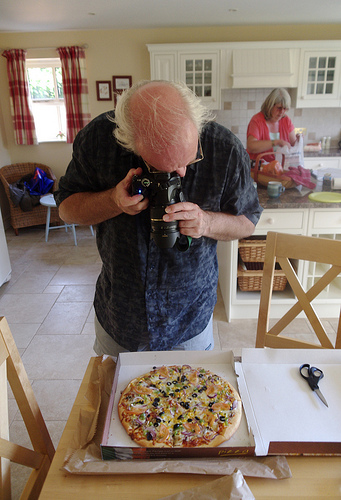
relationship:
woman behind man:
[245, 79, 299, 157] [67, 95, 250, 310]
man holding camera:
[67, 95, 250, 310] [137, 171, 195, 241]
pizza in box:
[134, 365, 244, 448] [104, 343, 274, 475]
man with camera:
[67, 95, 250, 310] [137, 171, 195, 241]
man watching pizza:
[67, 95, 250, 310] [134, 365, 244, 448]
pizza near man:
[134, 365, 244, 448] [67, 95, 250, 310]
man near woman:
[67, 95, 250, 310] [245, 79, 299, 157]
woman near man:
[245, 79, 299, 157] [67, 95, 250, 310]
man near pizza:
[67, 95, 250, 310] [134, 365, 244, 448]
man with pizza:
[67, 95, 250, 310] [134, 365, 244, 448]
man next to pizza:
[67, 95, 250, 310] [134, 365, 244, 448]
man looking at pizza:
[67, 95, 250, 310] [134, 365, 244, 448]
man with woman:
[67, 95, 250, 310] [245, 79, 299, 157]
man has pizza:
[67, 95, 250, 310] [134, 365, 244, 448]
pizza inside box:
[134, 365, 244, 448] [104, 343, 274, 475]